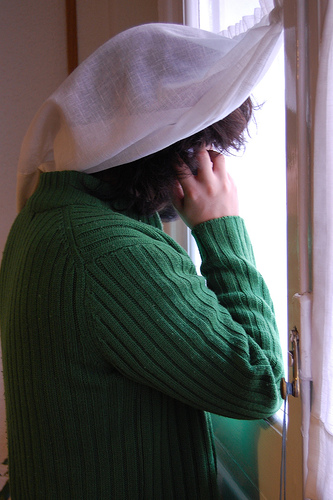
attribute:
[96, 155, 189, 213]
hair — brown, long, dark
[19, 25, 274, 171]
curtain — white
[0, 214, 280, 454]
sweater — green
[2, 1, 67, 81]
wall — brown, white, off-white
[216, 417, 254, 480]
shadow — green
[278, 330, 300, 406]
handle — metal, brass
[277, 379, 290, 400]
knob — gold, metal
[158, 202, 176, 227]
beard — black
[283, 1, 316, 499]
door — tan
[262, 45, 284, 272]
light — shining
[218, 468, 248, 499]
baseboard — white